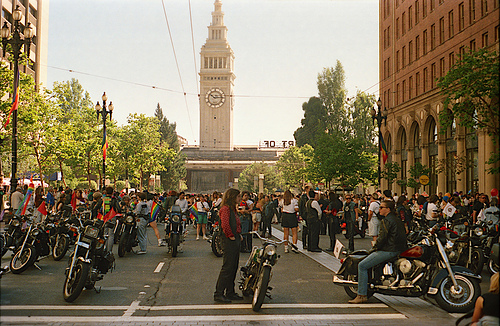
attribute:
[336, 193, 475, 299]
motorbike — parked, large, red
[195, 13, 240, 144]
clock tower — white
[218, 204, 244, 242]
woman — standing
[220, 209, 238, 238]
shirt — red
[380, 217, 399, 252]
leather — black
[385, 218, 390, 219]
jacket — black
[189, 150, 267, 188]
building — cream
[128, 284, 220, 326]
lines — white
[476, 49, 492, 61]
leaves — green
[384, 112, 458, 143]
windows — arched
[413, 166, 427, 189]
sign — yellow, round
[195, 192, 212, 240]
shorts — green, blue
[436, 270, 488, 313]
wheel — big